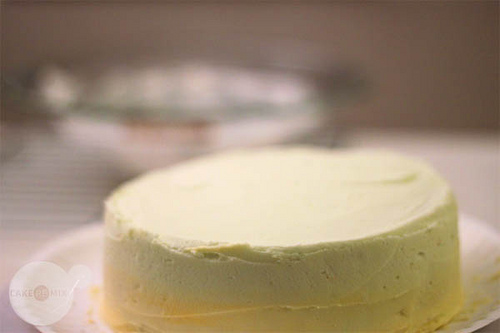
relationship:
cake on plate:
[97, 146, 465, 330] [4, 191, 495, 329]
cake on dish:
[97, 146, 465, 330] [6, 213, 500, 332]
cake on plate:
[97, 146, 465, 330] [25, 213, 499, 330]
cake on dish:
[97, 146, 465, 333] [2, 203, 497, 331]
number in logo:
[29, 275, 54, 305] [2, 257, 141, 319]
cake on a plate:
[97, 146, 465, 333] [444, 308, 498, 333]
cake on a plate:
[97, 146, 465, 330] [124, 221, 451, 333]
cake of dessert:
[97, 146, 465, 333] [17, 104, 471, 330]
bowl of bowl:
[31, 56, 372, 178] [19, 32, 420, 179]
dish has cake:
[6, 213, 500, 332] [97, 146, 465, 333]